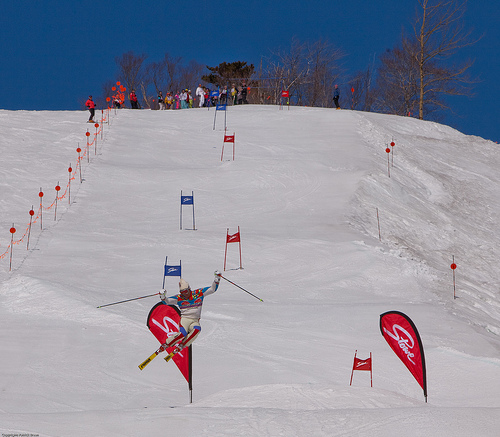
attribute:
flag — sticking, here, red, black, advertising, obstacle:
[334, 343, 394, 419]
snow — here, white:
[294, 227, 372, 323]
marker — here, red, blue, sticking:
[135, 190, 207, 214]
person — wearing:
[158, 279, 212, 318]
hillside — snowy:
[135, 122, 438, 351]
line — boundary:
[14, 144, 77, 195]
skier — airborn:
[121, 299, 211, 365]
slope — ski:
[146, 167, 268, 368]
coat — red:
[115, 87, 148, 116]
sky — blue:
[67, 14, 165, 67]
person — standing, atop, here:
[336, 91, 353, 104]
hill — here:
[117, 50, 274, 182]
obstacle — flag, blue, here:
[200, 210, 276, 286]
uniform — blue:
[151, 274, 217, 338]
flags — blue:
[149, 179, 204, 302]